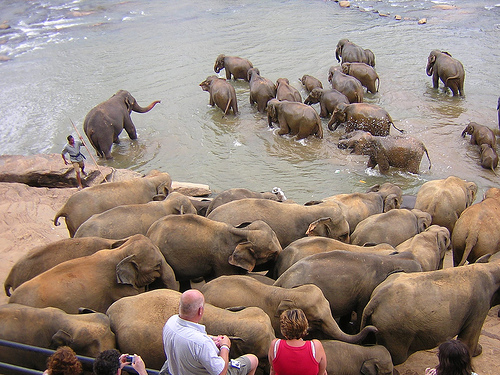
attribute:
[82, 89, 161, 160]
elephant — gray, large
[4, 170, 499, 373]
elephants — herding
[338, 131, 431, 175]
elephant — playing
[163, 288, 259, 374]
man — balding, bald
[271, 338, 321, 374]
tank top — red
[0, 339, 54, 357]
guard rail — black, metal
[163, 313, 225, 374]
shirt — white